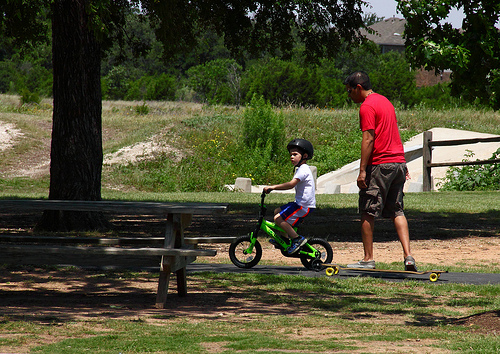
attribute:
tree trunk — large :
[31, 0, 119, 239]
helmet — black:
[285, 136, 315, 160]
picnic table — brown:
[0, 185, 247, 330]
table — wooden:
[13, 161, 250, 335]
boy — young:
[269, 133, 326, 253]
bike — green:
[202, 133, 349, 278]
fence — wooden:
[425, 121, 497, 198]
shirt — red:
[346, 88, 431, 166]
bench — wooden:
[2, 197, 233, 310]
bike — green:
[225, 185, 342, 279]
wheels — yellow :
[427, 271, 440, 283]